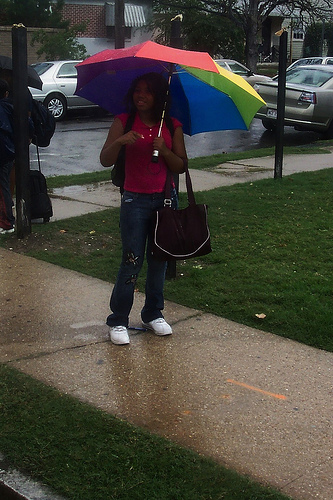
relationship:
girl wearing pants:
[100, 73, 189, 346] [108, 187, 180, 326]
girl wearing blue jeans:
[100, 73, 189, 346] [106, 187, 169, 327]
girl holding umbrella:
[100, 73, 189, 346] [72, 40, 267, 137]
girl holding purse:
[100, 73, 189, 346] [159, 153, 213, 264]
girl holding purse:
[100, 73, 189, 346] [145, 157, 213, 262]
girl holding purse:
[100, 73, 189, 346] [149, 154, 214, 258]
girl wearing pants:
[100, 73, 189, 346] [105, 185, 200, 342]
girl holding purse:
[100, 73, 189, 346] [148, 148, 217, 262]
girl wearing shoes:
[109, 108, 177, 343] [105, 321, 133, 343]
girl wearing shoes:
[109, 108, 177, 343] [138, 309, 173, 334]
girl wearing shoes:
[100, 73, 189, 346] [106, 316, 171, 345]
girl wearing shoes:
[100, 73, 189, 346] [109, 321, 130, 345]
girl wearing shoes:
[100, 73, 189, 346] [139, 309, 172, 336]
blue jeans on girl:
[101, 189, 167, 328] [98, 70, 175, 342]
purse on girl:
[145, 157, 213, 262] [100, 73, 189, 346]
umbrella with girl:
[72, 40, 267, 137] [100, 73, 189, 346]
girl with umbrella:
[100, 73, 189, 346] [71, 39, 267, 162]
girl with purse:
[100, 73, 189, 346] [149, 154, 214, 258]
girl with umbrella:
[100, 73, 189, 346] [72, 40, 267, 137]